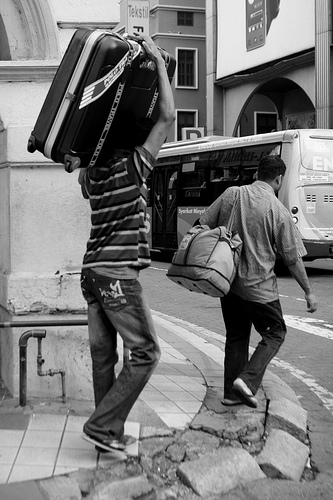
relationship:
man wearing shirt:
[174, 149, 315, 407] [184, 164, 311, 311]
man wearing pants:
[174, 149, 315, 407] [71, 254, 174, 465]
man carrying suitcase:
[78, 26, 179, 458] [6, 13, 245, 227]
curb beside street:
[187, 392, 302, 490] [139, 260, 332, 499]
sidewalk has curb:
[16, 286, 315, 493] [89, 423, 317, 485]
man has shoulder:
[198, 154, 320, 410] [223, 184, 244, 210]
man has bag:
[198, 154, 320, 410] [165, 222, 242, 298]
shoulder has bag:
[223, 184, 244, 210] [165, 222, 242, 298]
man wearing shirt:
[77, 32, 175, 451] [81, 145, 161, 269]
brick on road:
[194, 312, 210, 324] [146, 260, 332, 380]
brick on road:
[156, 293, 169, 307] [146, 260, 332, 380]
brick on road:
[306, 430, 332, 473] [146, 260, 332, 380]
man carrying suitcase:
[198, 154, 320, 410] [25, 25, 192, 195]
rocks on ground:
[76, 411, 264, 498] [155, 274, 224, 392]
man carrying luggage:
[198, 154, 320, 410] [168, 190, 258, 308]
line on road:
[265, 304, 332, 355] [113, 248, 331, 499]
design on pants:
[98, 280, 126, 313] [71, 254, 160, 455]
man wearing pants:
[77, 32, 175, 451] [71, 254, 160, 455]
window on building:
[172, 42, 206, 90] [94, 2, 224, 183]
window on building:
[172, 4, 198, 27] [94, 2, 224, 183]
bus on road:
[143, 134, 332, 263] [138, 259, 331, 498]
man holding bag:
[78, 26, 179, 458] [23, 29, 207, 198]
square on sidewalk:
[26, 411, 67, 430] [4, 391, 243, 487]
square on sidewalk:
[20, 429, 62, 447] [4, 391, 243, 487]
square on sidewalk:
[14, 447, 58, 466] [4, 391, 243, 487]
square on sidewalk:
[53, 448, 99, 469] [4, 391, 243, 487]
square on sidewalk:
[61, 430, 96, 450] [4, 391, 243, 487]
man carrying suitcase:
[198, 154, 320, 410] [24, 18, 182, 182]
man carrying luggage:
[78, 26, 179, 458] [28, 26, 176, 171]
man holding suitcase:
[78, 26, 179, 458] [24, 18, 182, 182]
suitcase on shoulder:
[24, 18, 182, 182] [122, 149, 151, 183]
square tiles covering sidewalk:
[27, 413, 76, 476] [104, 305, 220, 466]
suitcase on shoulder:
[24, 18, 182, 182] [78, 167, 103, 191]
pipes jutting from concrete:
[19, 330, 66, 407] [1, 397, 96, 415]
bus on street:
[119, 128, 330, 264] [138, 260, 332, 499]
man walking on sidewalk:
[198, 154, 320, 410] [0, 307, 309, 498]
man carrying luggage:
[198, 154, 320, 410] [28, 26, 176, 171]